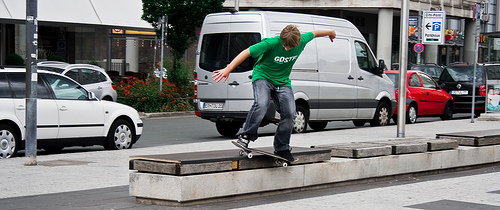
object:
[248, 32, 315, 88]
green shirt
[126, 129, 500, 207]
bench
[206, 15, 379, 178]
skateboarding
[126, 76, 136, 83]
flowers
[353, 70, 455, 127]
car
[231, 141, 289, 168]
skateboard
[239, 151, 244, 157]
wheels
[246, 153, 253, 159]
wheels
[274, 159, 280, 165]
wheels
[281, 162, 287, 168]
wheels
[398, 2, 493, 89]
buidings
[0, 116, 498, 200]
sidewalk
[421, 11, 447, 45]
sign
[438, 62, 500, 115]
car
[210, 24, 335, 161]
boy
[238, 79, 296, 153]
jeans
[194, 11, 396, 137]
van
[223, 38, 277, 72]
arms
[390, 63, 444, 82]
car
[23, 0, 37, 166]
pole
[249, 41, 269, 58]
sleeve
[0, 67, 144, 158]
car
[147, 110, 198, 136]
road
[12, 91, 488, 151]
street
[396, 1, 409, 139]
pole